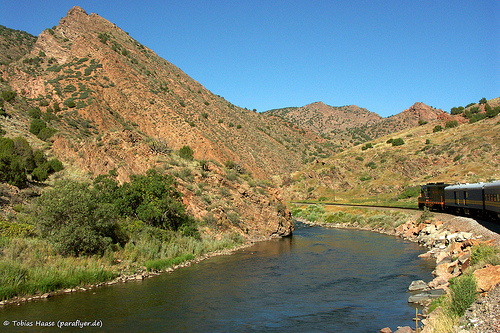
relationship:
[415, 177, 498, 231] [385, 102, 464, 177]
train in hill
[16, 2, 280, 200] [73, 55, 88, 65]
hill has tree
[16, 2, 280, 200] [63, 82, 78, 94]
hill has tree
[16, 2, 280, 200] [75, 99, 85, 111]
hill has tree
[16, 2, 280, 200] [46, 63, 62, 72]
hill has tree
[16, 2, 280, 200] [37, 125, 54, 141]
hill has tree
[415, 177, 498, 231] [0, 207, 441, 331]
train around river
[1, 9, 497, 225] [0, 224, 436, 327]
hills near river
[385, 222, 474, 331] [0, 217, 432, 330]
stones near water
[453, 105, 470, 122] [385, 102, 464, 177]
bushes on hill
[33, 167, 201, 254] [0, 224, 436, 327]
bush growing by river